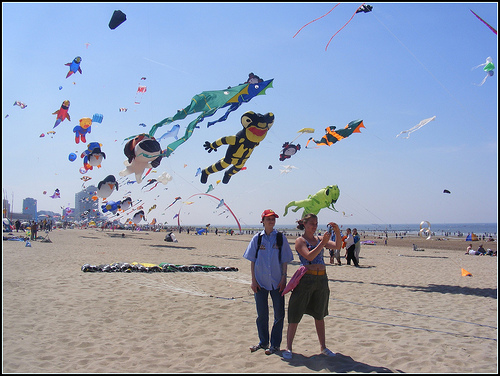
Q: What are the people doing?
A: Flying kites.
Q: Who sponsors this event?
A: The kite vendors.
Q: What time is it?
A: Noon.